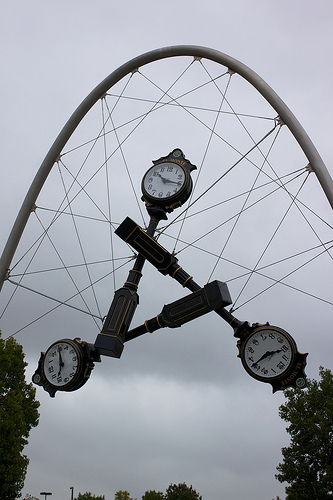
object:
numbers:
[277, 361, 285, 369]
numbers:
[281, 344, 289, 352]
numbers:
[260, 334, 267, 340]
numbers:
[248, 346, 254, 352]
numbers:
[64, 377, 69, 382]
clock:
[141, 160, 193, 202]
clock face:
[141, 148, 197, 213]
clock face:
[236, 322, 309, 394]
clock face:
[32, 337, 101, 397]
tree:
[272, 365, 333, 500]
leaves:
[277, 365, 333, 500]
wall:
[278, 115, 286, 125]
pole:
[114, 216, 241, 331]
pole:
[125, 280, 232, 343]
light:
[40, 492, 52, 495]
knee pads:
[140, 148, 197, 236]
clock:
[241, 325, 297, 381]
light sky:
[24, 360, 228, 412]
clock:
[41, 338, 83, 389]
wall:
[147, 92, 180, 114]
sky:
[0, 0, 332, 500]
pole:
[93, 215, 158, 360]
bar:
[0, 45, 333, 290]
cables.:
[225, 240, 333, 283]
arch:
[0, 45, 333, 293]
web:
[0, 59, 333, 342]